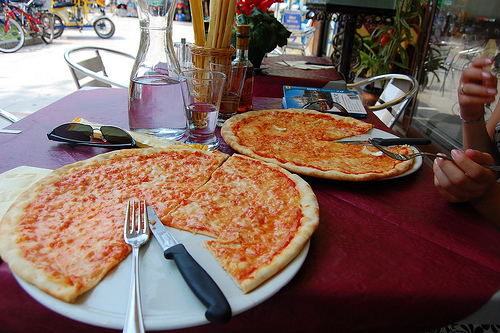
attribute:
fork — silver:
[122, 195, 154, 333]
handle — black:
[162, 241, 235, 328]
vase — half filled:
[124, 1, 193, 143]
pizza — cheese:
[2, 142, 330, 309]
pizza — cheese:
[214, 103, 423, 185]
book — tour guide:
[277, 78, 371, 121]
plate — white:
[6, 229, 318, 331]